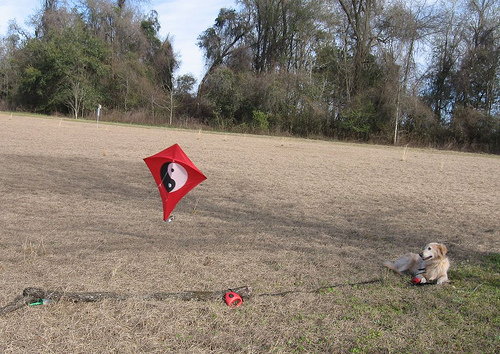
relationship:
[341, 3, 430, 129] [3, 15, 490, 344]
tree in field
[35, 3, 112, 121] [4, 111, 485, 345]
tree on field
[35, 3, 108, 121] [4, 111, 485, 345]
tree within field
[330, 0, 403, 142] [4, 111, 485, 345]
tree in a field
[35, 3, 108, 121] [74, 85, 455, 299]
tree in a field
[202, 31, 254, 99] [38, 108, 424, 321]
tree in a field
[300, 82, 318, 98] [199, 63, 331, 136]
leaves on tree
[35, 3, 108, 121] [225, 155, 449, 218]
tree in field